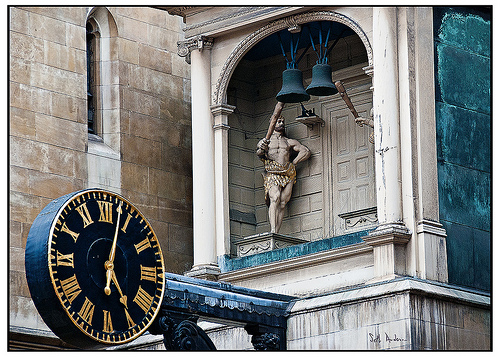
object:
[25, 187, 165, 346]
clock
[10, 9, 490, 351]
building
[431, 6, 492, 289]
marks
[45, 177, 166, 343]
roman numerals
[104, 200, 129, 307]
hands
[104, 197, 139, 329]
5:03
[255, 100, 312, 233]
statue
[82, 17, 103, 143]
window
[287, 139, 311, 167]
arm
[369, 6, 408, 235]
pillar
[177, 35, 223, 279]
pillar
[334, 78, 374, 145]
statue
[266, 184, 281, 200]
thigh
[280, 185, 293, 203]
thigh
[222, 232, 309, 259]
pedestal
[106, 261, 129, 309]
hour hand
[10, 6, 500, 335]
wall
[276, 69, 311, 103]
bell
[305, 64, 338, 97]
bell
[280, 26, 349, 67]
ropes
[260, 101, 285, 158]
weapon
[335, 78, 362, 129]
weapon